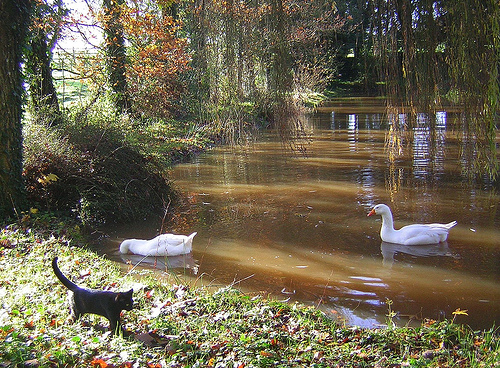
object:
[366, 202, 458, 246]
duck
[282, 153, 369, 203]
water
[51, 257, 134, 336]
cat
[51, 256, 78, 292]
tail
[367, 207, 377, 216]
beak